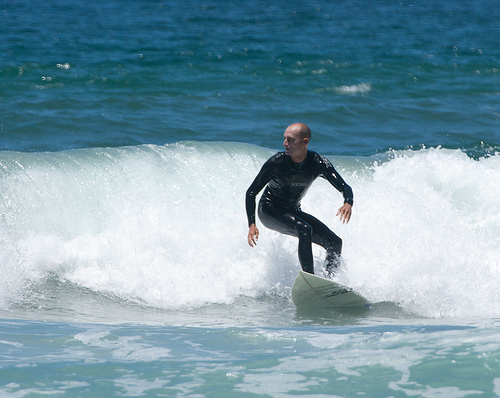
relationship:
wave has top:
[0, 144, 499, 336] [2, 130, 498, 184]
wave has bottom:
[0, 144, 499, 336] [0, 262, 499, 321]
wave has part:
[0, 144, 499, 336] [367, 137, 498, 177]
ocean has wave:
[0, 3, 499, 397] [0, 144, 499, 336]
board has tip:
[287, 266, 372, 319] [288, 264, 322, 288]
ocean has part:
[0, 3, 499, 397] [367, 137, 498, 177]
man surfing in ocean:
[242, 120, 356, 281] [0, 3, 499, 397]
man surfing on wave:
[242, 120, 356, 281] [0, 144, 499, 336]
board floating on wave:
[287, 266, 372, 319] [0, 144, 499, 336]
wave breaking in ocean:
[0, 144, 499, 336] [0, 3, 499, 397]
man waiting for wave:
[242, 120, 356, 281] [0, 144, 499, 336]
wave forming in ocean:
[0, 144, 499, 336] [0, 3, 499, 397]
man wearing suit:
[242, 120, 356, 281] [244, 152, 354, 283]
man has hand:
[242, 120, 356, 281] [337, 200, 357, 221]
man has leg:
[242, 120, 356, 281] [260, 203, 317, 275]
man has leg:
[242, 120, 356, 281] [294, 210, 343, 282]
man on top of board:
[242, 120, 356, 281] [287, 266, 372, 319]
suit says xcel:
[244, 152, 354, 283] [287, 177, 313, 195]